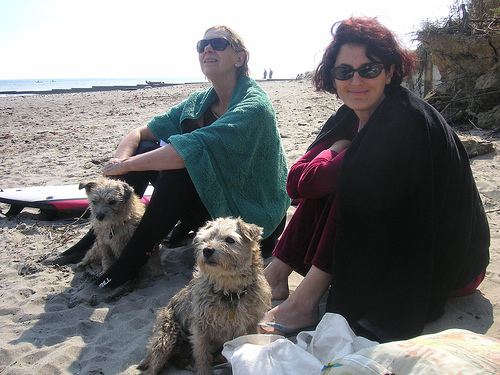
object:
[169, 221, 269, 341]
dog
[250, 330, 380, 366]
towel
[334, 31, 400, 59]
hair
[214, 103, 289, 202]
towel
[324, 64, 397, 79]
shades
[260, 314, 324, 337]
flip flops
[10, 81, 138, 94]
water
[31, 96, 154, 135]
sand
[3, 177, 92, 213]
surfboard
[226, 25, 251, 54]
hair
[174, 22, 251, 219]
woman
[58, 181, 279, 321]
dogs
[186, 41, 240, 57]
sunglasses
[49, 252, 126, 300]
feet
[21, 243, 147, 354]
sand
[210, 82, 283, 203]
shawl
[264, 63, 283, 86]
people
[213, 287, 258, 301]
collar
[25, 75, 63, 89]
people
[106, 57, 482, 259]
women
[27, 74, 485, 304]
beach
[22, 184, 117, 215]
device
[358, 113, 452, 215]
towel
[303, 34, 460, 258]
woman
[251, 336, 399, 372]
bag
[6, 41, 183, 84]
ocean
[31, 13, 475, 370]
photo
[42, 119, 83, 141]
footprints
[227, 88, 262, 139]
shoulders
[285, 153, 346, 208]
shirt